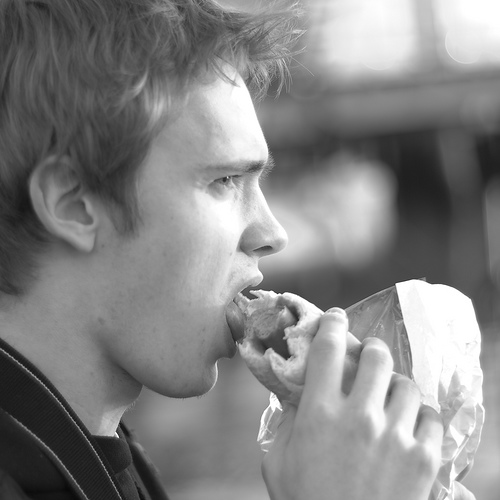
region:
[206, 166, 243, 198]
the man's eye is open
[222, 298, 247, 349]
the man's tongue is touching the hot dog bun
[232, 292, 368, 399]
a hot dog in a bun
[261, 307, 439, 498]
hand holding a hot dog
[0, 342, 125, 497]
a black strap with white trim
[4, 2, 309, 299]
the man's hair is tousled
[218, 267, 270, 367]
the man's mouth is open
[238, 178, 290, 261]
the man has a nose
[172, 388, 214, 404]
stubble on the man's chin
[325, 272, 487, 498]
the wrapper is celophane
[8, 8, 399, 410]
a man eating a hotdog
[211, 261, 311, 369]
a mouth eating a hotdog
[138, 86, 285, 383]
the face on a man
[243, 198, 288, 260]
the nose on a man's face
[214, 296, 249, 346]
the tongue on a man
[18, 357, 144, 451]
the neck on a man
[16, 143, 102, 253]
the ear on a man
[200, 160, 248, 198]
the eye on a man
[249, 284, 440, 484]
a hand holding a hotdog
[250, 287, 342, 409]
a partially eaten hotdog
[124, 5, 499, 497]
A background has light shades and is fuzzy.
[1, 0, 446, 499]
Man is eating a hot dog.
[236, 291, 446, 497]
Hand is holding a hot dog.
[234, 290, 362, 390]
Hot dog with a bite out of it.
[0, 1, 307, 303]
Man has brown hair sticking out in front.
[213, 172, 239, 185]
An eye that is open looking straight ahead.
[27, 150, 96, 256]
Human ear partly covered by hair.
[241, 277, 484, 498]
Hand holding hot dog and a package.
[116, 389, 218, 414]
Fuzz on front of neck and bottom of chin.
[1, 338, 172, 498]
Man wearing a dark shirt with white stitching.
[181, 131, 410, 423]
man eating a hog dog in a bun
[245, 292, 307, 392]
hot dog in a bun with a bite mark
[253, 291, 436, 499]
hand holding a hot dog in a bun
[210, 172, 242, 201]
a man's right eye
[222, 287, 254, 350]
a man opening his mouth getting ready for a bite of food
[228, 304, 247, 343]
a man's tongue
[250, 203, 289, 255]
a man's nose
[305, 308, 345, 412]
a man's right index finger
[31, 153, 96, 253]
a man's right ear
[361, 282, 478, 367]
plastic wrapper that's wrapped around a hot dog and its bun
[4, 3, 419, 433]
man eating sausage and bun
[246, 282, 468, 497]
hand holding bun and sausage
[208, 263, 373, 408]
mouth open to eat food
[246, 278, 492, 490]
man holding sandwich in wrapper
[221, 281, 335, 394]
tongue reaching for food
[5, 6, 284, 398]
man's face in profile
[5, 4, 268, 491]
man with strap around neck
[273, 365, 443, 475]
knuckles on man's hand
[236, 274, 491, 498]
plastic wrapper around sandwich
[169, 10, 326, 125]
hair bangs sticking out